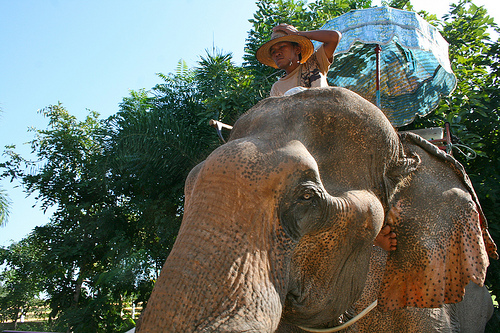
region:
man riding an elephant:
[198, 9, 376, 222]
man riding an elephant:
[240, 19, 371, 160]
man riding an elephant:
[232, 8, 333, 108]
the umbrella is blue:
[325, 7, 491, 171]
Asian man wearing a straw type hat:
[235, 16, 361, 91]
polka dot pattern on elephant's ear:
[375, 138, 496, 321]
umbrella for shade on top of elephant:
[310, 8, 477, 136]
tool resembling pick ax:
[197, 105, 243, 159]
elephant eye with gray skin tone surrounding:
[272, 161, 352, 241]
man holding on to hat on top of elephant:
[191, 11, 352, 151]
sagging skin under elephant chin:
[273, 236, 378, 330]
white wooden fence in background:
[2, 296, 145, 327]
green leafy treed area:
[1, 93, 178, 318]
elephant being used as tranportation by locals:
[128, 1, 487, 329]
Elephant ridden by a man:
[129, 83, 494, 332]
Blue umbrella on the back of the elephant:
[297, 6, 459, 129]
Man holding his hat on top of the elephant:
[251, 22, 344, 98]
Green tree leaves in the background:
[0, 48, 259, 331]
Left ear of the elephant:
[380, 128, 499, 310]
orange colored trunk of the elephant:
[137, 148, 301, 331]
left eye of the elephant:
[295, 186, 318, 207]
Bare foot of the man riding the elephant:
[368, 221, 400, 253]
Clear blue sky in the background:
[0, 1, 247, 137]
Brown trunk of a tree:
[70, 265, 85, 309]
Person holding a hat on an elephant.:
[262, 11, 318, 56]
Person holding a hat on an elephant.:
[360, 20, 440, 90]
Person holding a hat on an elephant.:
[1, 11, 101, 62]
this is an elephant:
[177, 107, 427, 331]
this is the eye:
[305, 180, 320, 201]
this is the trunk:
[166, 231, 266, 331]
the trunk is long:
[163, 215, 273, 330]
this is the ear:
[394, 154, 478, 282]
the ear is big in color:
[390, 158, 470, 289]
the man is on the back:
[257, 14, 340, 101]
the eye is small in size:
[298, 184, 318, 201]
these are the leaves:
[94, 104, 181, 180]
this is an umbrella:
[389, 21, 432, 48]